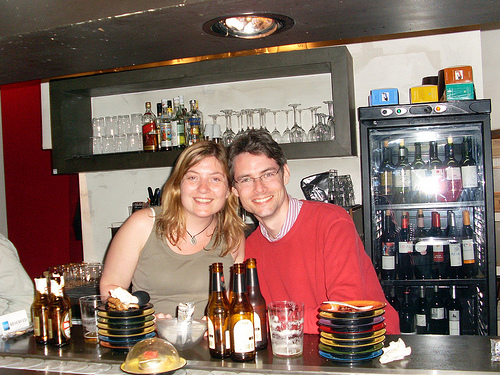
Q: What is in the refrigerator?
A: Bottles of wine.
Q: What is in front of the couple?
A: Beer bottles.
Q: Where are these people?
A: At a bar.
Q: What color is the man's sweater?
A: Red.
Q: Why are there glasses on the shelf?
A: For making and serving drinks.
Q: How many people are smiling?
A: Two.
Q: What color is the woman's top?
A: Beige.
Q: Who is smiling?
A: A young couple.